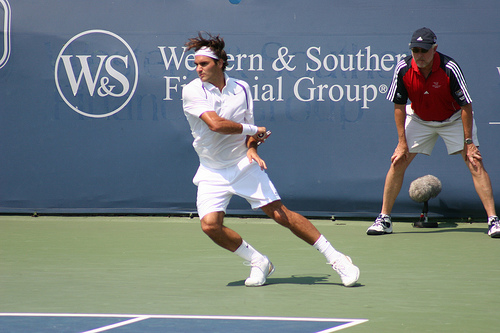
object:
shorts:
[404, 105, 480, 155]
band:
[195, 46, 226, 62]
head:
[194, 45, 228, 81]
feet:
[334, 256, 360, 286]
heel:
[263, 260, 274, 271]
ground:
[0, 216, 498, 331]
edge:
[331, 318, 369, 327]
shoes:
[244, 255, 274, 287]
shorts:
[192, 159, 281, 221]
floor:
[0, 216, 500, 333]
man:
[180, 47, 358, 287]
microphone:
[409, 174, 442, 228]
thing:
[408, 175, 443, 227]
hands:
[391, 144, 409, 166]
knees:
[203, 207, 290, 235]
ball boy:
[366, 27, 500, 238]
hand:
[464, 144, 483, 167]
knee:
[390, 158, 405, 169]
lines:
[0, 312, 368, 333]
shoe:
[488, 215, 499, 238]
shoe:
[367, 215, 394, 236]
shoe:
[330, 256, 359, 286]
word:
[293, 77, 377, 109]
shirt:
[386, 52, 471, 122]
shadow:
[226, 273, 365, 287]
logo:
[417, 36, 423, 41]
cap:
[409, 27, 436, 50]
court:
[0, 214, 500, 333]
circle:
[54, 29, 139, 117]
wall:
[0, 0, 500, 222]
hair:
[186, 30, 229, 72]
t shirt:
[179, 77, 255, 170]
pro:
[174, 39, 364, 291]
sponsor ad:
[53, 28, 406, 118]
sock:
[313, 233, 340, 263]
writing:
[156, 45, 407, 109]